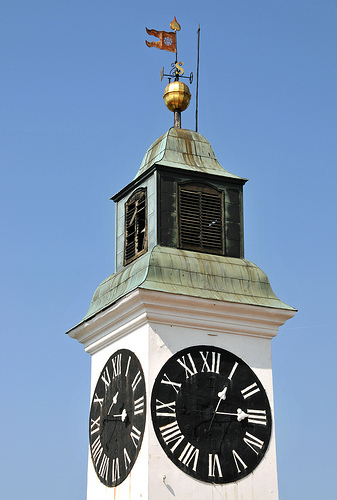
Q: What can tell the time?
A: The clock.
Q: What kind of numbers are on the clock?
A: Roman numerals.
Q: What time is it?
A: 1:15.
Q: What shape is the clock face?
A: Round.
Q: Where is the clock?
A: On the building.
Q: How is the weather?
A: Clear.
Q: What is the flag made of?
A: Metal.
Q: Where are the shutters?
A: Top of the building.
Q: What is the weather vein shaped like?
A: Flag.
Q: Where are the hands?
A: On the clock.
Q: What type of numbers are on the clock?
A: Roman numerals.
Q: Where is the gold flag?
A: On the top of the tower.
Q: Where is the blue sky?
A: Behind the tower.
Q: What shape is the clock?
A: Circle.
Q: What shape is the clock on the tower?
A: Circle.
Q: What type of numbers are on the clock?
A: Roman numerals.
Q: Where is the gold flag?
A: On the very top of the building.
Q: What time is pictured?
A: 1:15.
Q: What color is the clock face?
A: Black.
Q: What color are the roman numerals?
A: White.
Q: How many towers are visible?
A: 1.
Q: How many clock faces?
A: 2.